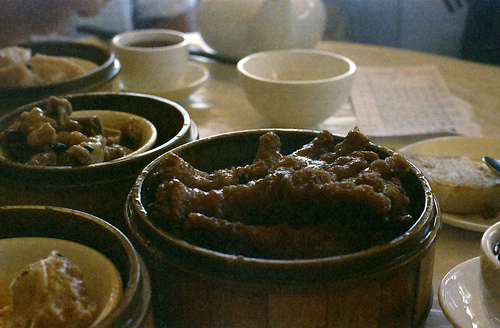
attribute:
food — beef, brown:
[155, 126, 414, 243]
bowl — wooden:
[123, 127, 434, 327]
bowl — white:
[237, 46, 357, 130]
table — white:
[1, 39, 500, 327]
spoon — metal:
[485, 158, 500, 177]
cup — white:
[112, 28, 190, 86]